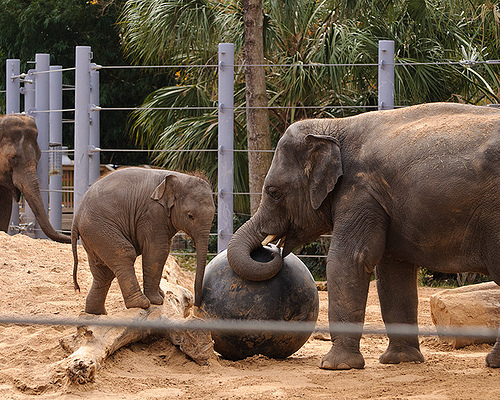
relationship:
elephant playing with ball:
[226, 101, 499, 369] [202, 245, 320, 360]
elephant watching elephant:
[2, 113, 80, 244] [226, 101, 499, 369]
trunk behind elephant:
[243, 0, 273, 222] [226, 101, 499, 369]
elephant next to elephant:
[226, 101, 499, 369] [72, 167, 215, 314]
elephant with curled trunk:
[226, 101, 499, 369] [227, 208, 282, 282]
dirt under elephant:
[3, 227, 499, 399] [226, 101, 499, 369]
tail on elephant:
[71, 215, 82, 293] [72, 167, 215, 314]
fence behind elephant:
[1, 40, 499, 258] [72, 167, 215, 314]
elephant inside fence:
[226, 101, 499, 369] [1, 40, 499, 258]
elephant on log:
[72, 167, 215, 314] [10, 279, 226, 393]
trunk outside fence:
[243, 0, 273, 222] [1, 40, 499, 258]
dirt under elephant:
[3, 227, 499, 399] [2, 113, 80, 244]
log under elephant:
[10, 279, 226, 393] [72, 167, 215, 314]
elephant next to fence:
[2, 113, 80, 244] [1, 40, 499, 258]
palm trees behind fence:
[101, 1, 498, 287] [1, 40, 499, 258]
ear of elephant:
[152, 174, 175, 210] [72, 167, 215, 314]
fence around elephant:
[1, 40, 499, 258] [2, 113, 80, 244]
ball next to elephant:
[202, 245, 320, 360] [2, 113, 80, 244]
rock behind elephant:
[431, 280, 499, 347] [226, 101, 499, 369]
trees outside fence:
[0, 0, 203, 161] [1, 40, 499, 258]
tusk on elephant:
[259, 232, 275, 247] [226, 101, 499, 369]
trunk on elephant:
[13, 164, 77, 243] [2, 113, 80, 244]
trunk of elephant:
[192, 221, 212, 309] [72, 167, 215, 314]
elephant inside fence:
[72, 167, 215, 314] [1, 40, 499, 258]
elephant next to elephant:
[72, 167, 215, 314] [226, 101, 499, 369]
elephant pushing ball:
[72, 167, 215, 314] [202, 245, 320, 360]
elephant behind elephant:
[2, 113, 80, 244] [72, 167, 215, 314]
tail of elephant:
[71, 215, 82, 293] [72, 167, 215, 314]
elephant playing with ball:
[72, 167, 215, 314] [202, 245, 320, 360]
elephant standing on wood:
[72, 167, 215, 314] [13, 305, 223, 394]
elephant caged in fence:
[226, 101, 499, 369] [1, 40, 499, 258]